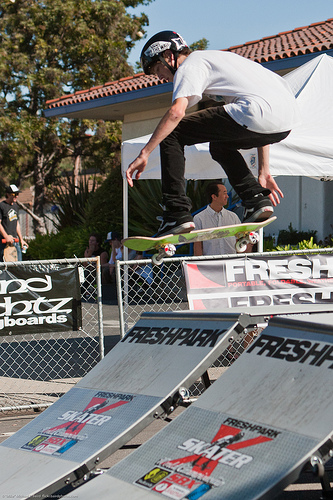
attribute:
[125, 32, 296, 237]
man — skateboarding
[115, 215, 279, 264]
skateboard — green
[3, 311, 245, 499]
ramp — metal, grey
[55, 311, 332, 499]
ramp — metal, grey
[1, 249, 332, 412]
fence — metal, short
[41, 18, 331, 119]
roof — pink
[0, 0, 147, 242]
tree — green, large, tall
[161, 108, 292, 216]
pants — black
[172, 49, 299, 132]
shirt — white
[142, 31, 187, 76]
helmet — white, black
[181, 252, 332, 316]
sign — white, black, red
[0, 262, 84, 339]
sign — white, black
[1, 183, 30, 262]
man — standing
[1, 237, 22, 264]
skateboard — yellow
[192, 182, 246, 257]
man — standing, smiling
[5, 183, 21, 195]
hat — white, black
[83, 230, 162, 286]
people — sitting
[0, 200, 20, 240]
shirt — black